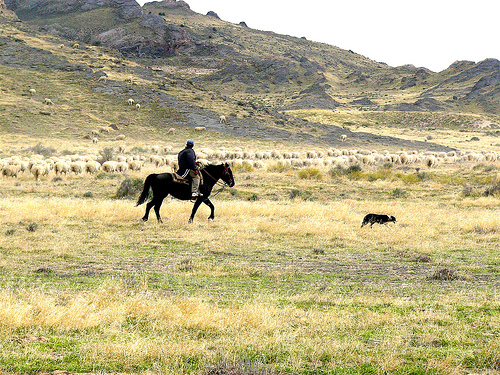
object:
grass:
[0, 109, 500, 371]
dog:
[360, 212, 398, 228]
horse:
[133, 160, 235, 223]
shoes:
[191, 190, 206, 197]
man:
[176, 139, 207, 197]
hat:
[185, 140, 194, 145]